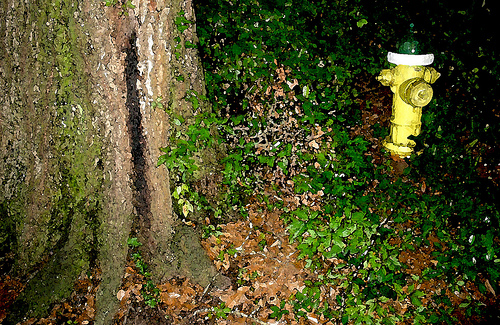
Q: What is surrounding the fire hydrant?
A: Plants.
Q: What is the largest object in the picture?
A: A tree.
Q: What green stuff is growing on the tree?
A: Moss.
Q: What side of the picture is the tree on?
A: The left.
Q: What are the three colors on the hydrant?
A: Yellow white and green.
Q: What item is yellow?
A: Hydrant.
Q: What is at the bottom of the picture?
A: Tree base.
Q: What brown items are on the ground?
A: Dead leaves.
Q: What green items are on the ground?
A: Leaves.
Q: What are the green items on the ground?
A: Leaves.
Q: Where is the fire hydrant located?
A: In leaves.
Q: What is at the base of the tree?
A: Dirt.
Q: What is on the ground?
A: A fire hydrant.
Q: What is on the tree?
A: Moss.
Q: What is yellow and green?
A: Fire hydrant.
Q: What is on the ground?
A: Dead leaves.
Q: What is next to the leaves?
A: The tree.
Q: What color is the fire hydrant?
A: Yellow.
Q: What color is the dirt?
A: Brown.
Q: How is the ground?
A: Dirty.